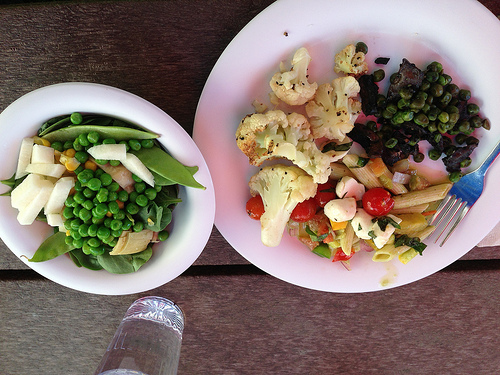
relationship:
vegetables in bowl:
[85, 144, 125, 160] [0, 77, 216, 297]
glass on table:
[93, 295, 189, 374] [0, 2, 498, 370]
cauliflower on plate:
[247, 165, 317, 246] [194, 0, 499, 300]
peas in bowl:
[56, 133, 171, 253] [0, 77, 216, 297]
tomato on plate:
[361, 188, 394, 217] [194, 0, 499, 300]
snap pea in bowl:
[41, 121, 159, 143] [0, 77, 216, 297]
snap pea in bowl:
[130, 148, 209, 190] [0, 77, 216, 297]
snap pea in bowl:
[145, 161, 195, 188] [0, 77, 216, 297]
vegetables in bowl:
[0, 113, 202, 272] [0, 77, 216, 297]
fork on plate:
[425, 148, 498, 245] [194, 0, 499, 300]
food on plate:
[234, 36, 494, 269] [194, 0, 499, 300]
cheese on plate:
[323, 194, 359, 222] [194, 0, 499, 300]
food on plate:
[303, 76, 360, 141] [194, 0, 499, 300]